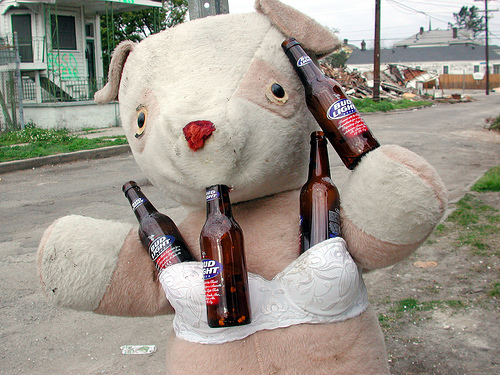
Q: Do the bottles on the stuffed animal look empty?
A: Yes, the bottles are empty.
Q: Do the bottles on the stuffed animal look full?
A: No, the bottles are empty.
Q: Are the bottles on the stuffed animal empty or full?
A: The bottles are empty.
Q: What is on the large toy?
A: The bottles are on the stuffed animal.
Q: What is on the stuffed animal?
A: The bottles are on the stuffed animal.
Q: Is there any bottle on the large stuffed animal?
A: Yes, there are bottles on the stuffed animal.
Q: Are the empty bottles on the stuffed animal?
A: Yes, the bottles are on the stuffed animal.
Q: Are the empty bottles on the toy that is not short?
A: Yes, the bottles are on the stuffed animal.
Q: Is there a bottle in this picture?
A: Yes, there is a bottle.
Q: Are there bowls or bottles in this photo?
A: Yes, there is a bottle.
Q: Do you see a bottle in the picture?
A: Yes, there is a bottle.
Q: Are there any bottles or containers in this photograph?
A: Yes, there is a bottle.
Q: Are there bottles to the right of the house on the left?
A: Yes, there is a bottle to the right of the house.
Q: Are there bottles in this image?
A: Yes, there is a bottle.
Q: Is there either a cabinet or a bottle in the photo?
A: Yes, there is a bottle.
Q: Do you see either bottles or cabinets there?
A: Yes, there is a bottle.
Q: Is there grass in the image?
A: Yes, there is grass.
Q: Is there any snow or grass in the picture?
A: Yes, there is grass.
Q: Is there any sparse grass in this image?
A: Yes, there is sparse grass.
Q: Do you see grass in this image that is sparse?
A: Yes, there is grass that is sparse.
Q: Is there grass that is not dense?
A: Yes, there is sparse grass.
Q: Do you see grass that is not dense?
A: Yes, there is sparse grass.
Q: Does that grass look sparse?
A: Yes, the grass is sparse.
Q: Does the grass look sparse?
A: Yes, the grass is sparse.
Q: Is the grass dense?
A: No, the grass is sparse.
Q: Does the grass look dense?
A: No, the grass is sparse.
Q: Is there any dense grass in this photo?
A: No, there is grass but it is sparse.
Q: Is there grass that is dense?
A: No, there is grass but it is sparse.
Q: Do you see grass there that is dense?
A: No, there is grass but it is sparse.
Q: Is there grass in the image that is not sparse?
A: No, there is grass but it is sparse.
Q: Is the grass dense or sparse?
A: The grass is sparse.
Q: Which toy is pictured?
A: The toy is a stuffed animal.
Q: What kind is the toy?
A: The toy is a stuffed animal.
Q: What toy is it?
A: The toy is a stuffed animal.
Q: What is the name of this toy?
A: This is a stuffed animal.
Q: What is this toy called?
A: This is a stuffed animal.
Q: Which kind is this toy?
A: This is a stuffed animal.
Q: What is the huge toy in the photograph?
A: The toy is a stuffed animal.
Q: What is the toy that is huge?
A: The toy is a stuffed animal.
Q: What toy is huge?
A: The toy is a stuffed animal.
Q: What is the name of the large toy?
A: The toy is a stuffed animal.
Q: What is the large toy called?
A: The toy is a stuffed animal.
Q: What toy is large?
A: The toy is a stuffed animal.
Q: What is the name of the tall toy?
A: The toy is a stuffed animal.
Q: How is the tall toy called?
A: The toy is a stuffed animal.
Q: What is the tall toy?
A: The toy is a stuffed animal.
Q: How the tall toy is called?
A: The toy is a stuffed animal.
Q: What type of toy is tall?
A: The toy is a stuffed animal.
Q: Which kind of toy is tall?
A: The toy is a stuffed animal.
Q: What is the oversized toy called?
A: The toy is a stuffed animal.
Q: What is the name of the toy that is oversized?
A: The toy is a stuffed animal.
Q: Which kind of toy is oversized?
A: The toy is a stuffed animal.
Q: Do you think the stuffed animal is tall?
A: Yes, the stuffed animal is tall.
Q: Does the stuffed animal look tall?
A: Yes, the stuffed animal is tall.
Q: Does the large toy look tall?
A: Yes, the stuffed animal is tall.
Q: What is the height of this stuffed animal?
A: The stuffed animal is tall.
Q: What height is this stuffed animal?
A: The stuffed animal is tall.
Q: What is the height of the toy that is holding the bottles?
A: The stuffed animal is tall.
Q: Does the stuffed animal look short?
A: No, the stuffed animal is tall.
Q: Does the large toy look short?
A: No, the stuffed animal is tall.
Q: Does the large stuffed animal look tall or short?
A: The stuffed animal is tall.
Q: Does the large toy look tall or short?
A: The stuffed animal is tall.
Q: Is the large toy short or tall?
A: The stuffed animal is tall.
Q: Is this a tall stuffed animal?
A: Yes, this is a tall stuffed animal.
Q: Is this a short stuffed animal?
A: No, this is a tall stuffed animal.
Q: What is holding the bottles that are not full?
A: The stuffed animal is holding the bottles.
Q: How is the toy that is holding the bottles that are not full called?
A: The toy is a stuffed animal.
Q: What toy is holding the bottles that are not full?
A: The toy is a stuffed animal.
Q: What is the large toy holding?
A: The stuffed animal is holding the bottles.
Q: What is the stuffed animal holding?
A: The stuffed animal is holding the bottles.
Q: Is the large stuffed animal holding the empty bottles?
A: Yes, the stuffed animal is holding the bottles.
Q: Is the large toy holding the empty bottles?
A: Yes, the stuffed animal is holding the bottles.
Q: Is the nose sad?
A: Yes, the nose is sad.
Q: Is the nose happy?
A: No, the nose is sad.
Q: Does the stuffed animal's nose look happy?
A: No, the nose is sad.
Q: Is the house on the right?
A: No, the house is on the left of the image.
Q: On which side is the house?
A: The house is on the left of the image.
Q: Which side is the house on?
A: The house is on the left of the image.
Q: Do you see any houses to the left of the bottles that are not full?
A: Yes, there is a house to the left of the bottles.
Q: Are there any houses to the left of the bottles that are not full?
A: Yes, there is a house to the left of the bottles.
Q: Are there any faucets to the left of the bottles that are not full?
A: No, there is a house to the left of the bottles.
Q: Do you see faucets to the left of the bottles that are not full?
A: No, there is a house to the left of the bottles.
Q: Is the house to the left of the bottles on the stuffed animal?
A: Yes, the house is to the left of the bottles.